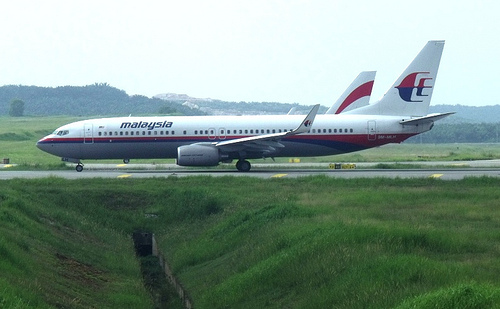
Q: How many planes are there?
A: Two.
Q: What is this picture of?
A: Airplane.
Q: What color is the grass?
A: Green.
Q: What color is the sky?
A: Blue.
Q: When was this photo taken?
A: During the day.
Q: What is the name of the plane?
A: Malaysia.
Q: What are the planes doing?
A: Sitting on runway.